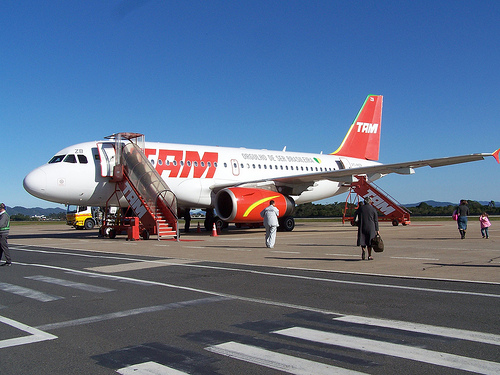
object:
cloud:
[0, 37, 317, 118]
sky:
[0, 0, 500, 92]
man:
[260, 200, 279, 248]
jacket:
[260, 205, 280, 228]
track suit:
[260, 205, 280, 226]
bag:
[452, 210, 459, 221]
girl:
[479, 213, 492, 240]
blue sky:
[0, 0, 499, 199]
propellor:
[214, 187, 296, 223]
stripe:
[242, 196, 280, 218]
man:
[353, 196, 380, 260]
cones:
[210, 223, 219, 236]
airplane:
[22, 94, 498, 242]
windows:
[247, 163, 251, 169]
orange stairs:
[116, 144, 179, 239]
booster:
[213, 187, 296, 223]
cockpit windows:
[47, 155, 88, 163]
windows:
[180, 160, 185, 166]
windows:
[187, 161, 191, 167]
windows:
[224, 162, 228, 169]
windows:
[158, 159, 163, 165]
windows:
[290, 166, 294, 171]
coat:
[353, 204, 379, 246]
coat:
[479, 217, 491, 228]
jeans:
[481, 226, 490, 237]